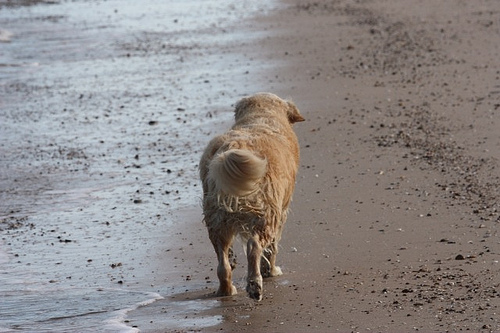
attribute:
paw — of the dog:
[246, 272, 262, 303]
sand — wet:
[30, 240, 127, 302]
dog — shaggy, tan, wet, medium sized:
[193, 92, 303, 302]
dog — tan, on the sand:
[198, 87, 308, 308]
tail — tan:
[210, 142, 270, 202]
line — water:
[191, 13, 267, 326]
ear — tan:
[281, 95, 305, 130]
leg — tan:
[198, 212, 242, 302]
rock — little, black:
[452, 250, 464, 267]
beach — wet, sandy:
[16, 15, 487, 326]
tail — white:
[202, 145, 267, 203]